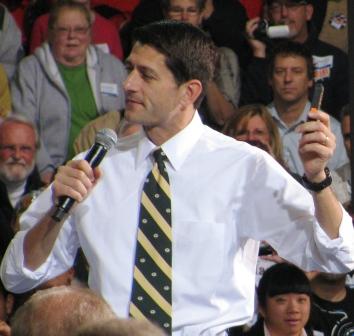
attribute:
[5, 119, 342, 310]
white shirt — long sleeve